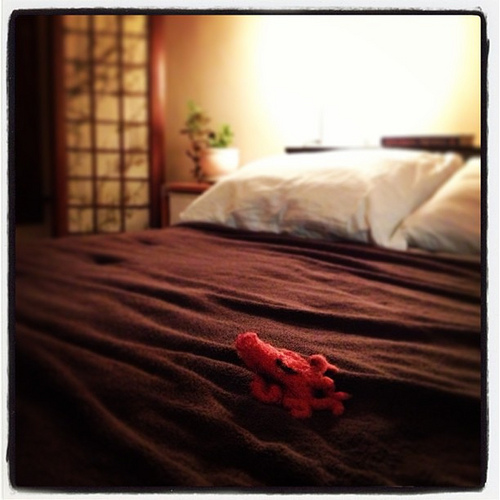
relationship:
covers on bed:
[11, 220, 483, 492] [10, 120, 493, 490]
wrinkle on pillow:
[352, 192, 392, 260] [177, 149, 461, 250]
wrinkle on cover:
[163, 393, 295, 465] [13, 216, 484, 488]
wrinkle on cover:
[212, 282, 466, 344] [13, 216, 484, 488]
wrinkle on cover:
[362, 352, 479, 404] [13, 216, 484, 488]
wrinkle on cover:
[34, 307, 174, 383] [13, 216, 484, 488]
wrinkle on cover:
[38, 352, 171, 461] [13, 216, 484, 488]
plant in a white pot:
[180, 102, 241, 186] [199, 145, 241, 179]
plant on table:
[173, 100, 253, 199] [161, 179, 211, 225]